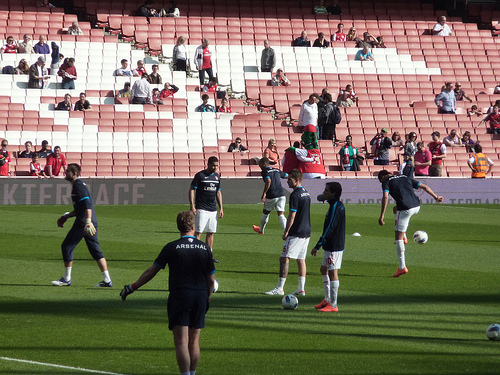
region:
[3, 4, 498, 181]
a bunch of seats for people to sit on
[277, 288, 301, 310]
a soccer ball on the ground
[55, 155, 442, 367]
soccer players standing aorund the field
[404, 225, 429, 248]
a soccer ball in the air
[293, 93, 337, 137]
two people standing up in the stands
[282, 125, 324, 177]
a person taking a photo with the mascot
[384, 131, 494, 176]
more people waiting for the game to start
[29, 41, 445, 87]
the white section of the seats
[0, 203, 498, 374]
the astroturf the people will play on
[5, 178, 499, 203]
the fence at the field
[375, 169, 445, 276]
Man kicking a soccer ball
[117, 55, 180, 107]
Crowd at a soccer game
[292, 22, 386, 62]
Crowd at a soccer game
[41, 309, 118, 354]
Green grass on soccer field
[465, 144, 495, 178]
Man wearing an orange vest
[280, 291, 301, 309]
Soccer ball on the ground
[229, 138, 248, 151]
Man wearing black sunglasses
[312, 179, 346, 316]
Man wearing white shorts and blue shirt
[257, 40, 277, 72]
Man with dark jacket on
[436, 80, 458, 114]
Man wearing a blue shirt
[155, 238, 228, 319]
man's shirt is black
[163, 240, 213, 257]
white letters on shirt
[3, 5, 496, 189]
people watching the players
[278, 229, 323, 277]
man's shorts are white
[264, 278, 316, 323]
ball on the grass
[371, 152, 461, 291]
man is kicking the ball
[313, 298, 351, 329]
man's shoes are orange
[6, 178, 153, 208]
gray letters on wall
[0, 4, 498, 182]
the chairs are white and red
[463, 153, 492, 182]
person wearing orange vest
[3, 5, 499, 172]
grandstands of a sports stadium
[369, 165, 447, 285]
A drilling soccer player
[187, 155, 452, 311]
Soccer players practicing on a field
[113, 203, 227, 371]
A man wearing an Arsenal t-shirt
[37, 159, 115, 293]
Man walking across a soccer field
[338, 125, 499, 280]
Audience watching a soccer game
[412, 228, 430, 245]
A bouncing soccer ball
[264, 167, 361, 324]
Two soccer players watching down-field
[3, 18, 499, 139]
Mostly empty seats with people watching soccer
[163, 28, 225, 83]
Two people looking for a seat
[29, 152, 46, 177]
kid in red and white sweater watching game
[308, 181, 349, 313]
soccer player wearing bright orange shoes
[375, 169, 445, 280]
soccer player kicking ball with right foot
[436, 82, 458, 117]
man in blue shirt standing watching game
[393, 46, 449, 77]
seats painted red and white for team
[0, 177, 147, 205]
advertising on back wall in light grey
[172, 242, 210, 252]
name of player on blue shirt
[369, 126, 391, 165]
man standing in seats with green cap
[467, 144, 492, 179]
referee standing against back grey wall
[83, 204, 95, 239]
player with thick white safety gloves